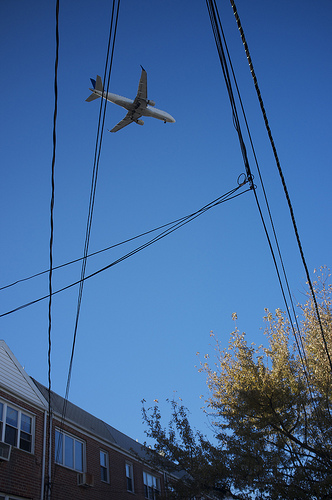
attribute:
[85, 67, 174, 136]
airplane — blue, white, flying, gray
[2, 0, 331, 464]
sky — blue, clear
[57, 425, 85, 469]
window — triple-paned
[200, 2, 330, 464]
wires — black, vertical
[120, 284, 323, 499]
tree — leafy, leaf covered, green, large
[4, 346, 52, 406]
siding — white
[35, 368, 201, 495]
roof — black, shingled, tiled, pitched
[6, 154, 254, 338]
wires — black, horizontal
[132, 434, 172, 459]
chimneys — white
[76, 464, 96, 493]
air conditioning uni — rusty, metal, very rusty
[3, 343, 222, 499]
building — brick, red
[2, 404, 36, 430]
blinds — half closed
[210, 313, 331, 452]
branch — leaf covered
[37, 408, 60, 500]
drainage pipe — white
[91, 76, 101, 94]
tail fin — blue